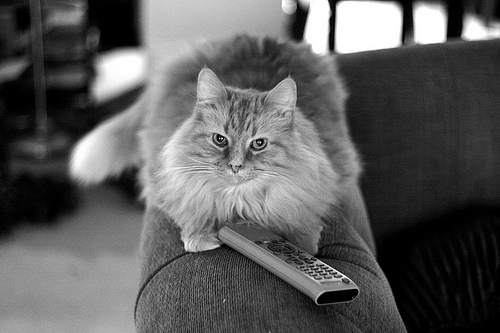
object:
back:
[285, 207, 406, 331]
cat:
[64, 28, 366, 256]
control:
[216, 221, 362, 307]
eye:
[205, 130, 232, 149]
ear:
[195, 65, 230, 103]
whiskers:
[161, 152, 220, 175]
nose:
[227, 159, 245, 173]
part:
[379, 85, 425, 130]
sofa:
[372, 50, 490, 239]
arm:
[140, 252, 371, 332]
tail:
[65, 85, 151, 188]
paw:
[179, 228, 224, 253]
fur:
[189, 46, 255, 71]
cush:
[404, 205, 453, 277]